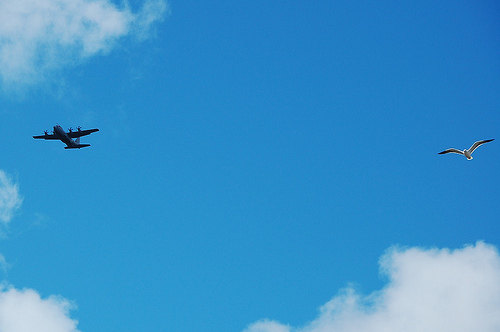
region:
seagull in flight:
[438, 138, 495, 159]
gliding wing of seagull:
[438, 148, 463, 155]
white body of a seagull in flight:
[461, 148, 472, 160]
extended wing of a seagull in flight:
[466, 138, 494, 152]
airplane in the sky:
[33, 124, 100, 149]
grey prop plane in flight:
[34, 125, 99, 148]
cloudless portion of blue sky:
[172, 1, 497, 136]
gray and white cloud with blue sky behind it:
[245, 245, 496, 325]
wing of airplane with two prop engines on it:
[65, 127, 96, 137]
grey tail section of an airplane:
[65, 138, 90, 149]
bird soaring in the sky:
[430, 133, 492, 168]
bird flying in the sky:
[429, 136, 496, 166]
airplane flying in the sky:
[28, 110, 113, 153]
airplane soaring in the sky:
[22, 120, 110, 160]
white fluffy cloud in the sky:
[3, 268, 74, 330]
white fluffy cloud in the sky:
[281, 247, 498, 328]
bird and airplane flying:
[22, 114, 497, 199]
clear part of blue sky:
[175, 117, 279, 209]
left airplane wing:
[66, 126, 102, 141]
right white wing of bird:
[436, 142, 466, 159]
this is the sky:
[231, 8, 363, 109]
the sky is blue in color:
[169, 173, 281, 250]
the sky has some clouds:
[236, 235, 498, 330]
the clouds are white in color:
[413, 263, 467, 320]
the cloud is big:
[5, 5, 162, 91]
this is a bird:
[434, 131, 496, 170]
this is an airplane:
[28, 110, 112, 162]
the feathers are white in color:
[449, 147, 464, 155]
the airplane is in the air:
[36, 125, 102, 152]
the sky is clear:
[171, 64, 283, 130]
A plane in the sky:
[26, 118, 111, 163]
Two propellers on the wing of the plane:
[65, 123, 85, 135]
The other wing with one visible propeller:
[28, 122, 53, 149]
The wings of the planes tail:
[61, 142, 96, 156]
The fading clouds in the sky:
[1, 1, 163, 84]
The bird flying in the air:
[424, 126, 494, 173]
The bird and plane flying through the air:
[1, 93, 496, 169]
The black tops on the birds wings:
[430, 133, 499, 167]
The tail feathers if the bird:
[465, 153, 475, 160]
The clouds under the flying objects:
[4, 228, 499, 330]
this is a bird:
[417, 110, 498, 187]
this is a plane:
[22, 112, 103, 158]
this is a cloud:
[193, 204, 496, 330]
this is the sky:
[113, 231, 166, 276]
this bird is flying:
[422, 123, 498, 170]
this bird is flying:
[26, 105, 114, 165]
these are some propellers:
[38, 123, 88, 135]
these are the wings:
[432, 137, 498, 162]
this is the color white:
[397, 277, 447, 316]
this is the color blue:
[113, 162, 157, 209]